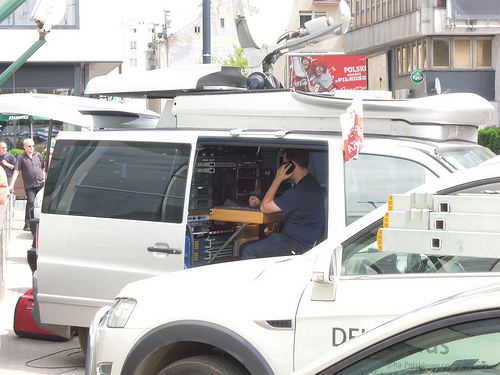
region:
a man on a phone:
[238, 156, 323, 256]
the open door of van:
[30, 113, 200, 337]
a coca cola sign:
[289, 54, 369, 109]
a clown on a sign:
[295, 47, 345, 100]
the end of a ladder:
[352, 168, 484, 283]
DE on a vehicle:
[314, 317, 363, 346]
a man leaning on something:
[2, 128, 48, 262]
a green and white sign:
[406, 68, 433, 85]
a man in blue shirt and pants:
[217, 169, 342, 269]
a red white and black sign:
[282, 54, 376, 102]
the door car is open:
[242, 154, 342, 263]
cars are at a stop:
[80, 87, 497, 332]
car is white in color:
[115, 242, 357, 371]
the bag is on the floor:
[8, 278, 67, 373]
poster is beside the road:
[285, 42, 388, 104]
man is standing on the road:
[9, 132, 47, 203]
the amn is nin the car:
[243, 145, 302, 256]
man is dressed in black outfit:
[252, 148, 310, 243]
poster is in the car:
[343, 99, 367, 181]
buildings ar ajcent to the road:
[343, 8, 493, 126]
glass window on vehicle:
[345, 317, 497, 372]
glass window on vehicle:
[349, 188, 496, 270]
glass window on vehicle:
[346, 150, 435, 230]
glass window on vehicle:
[439, 145, 493, 170]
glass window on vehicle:
[46, 140, 182, 224]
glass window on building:
[474, 38, 491, 65]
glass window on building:
[456, 39, 474, 67]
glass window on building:
[433, 37, 451, 67]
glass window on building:
[421, 40, 429, 67]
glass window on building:
[399, 47, 406, 72]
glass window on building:
[414, 45, 424, 67]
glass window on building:
[404, 46, 411, 70]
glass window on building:
[401, 45, 408, 75]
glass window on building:
[396, 48, 402, 74]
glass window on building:
[13, 1, 73, 26]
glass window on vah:
[45, 138, 184, 224]